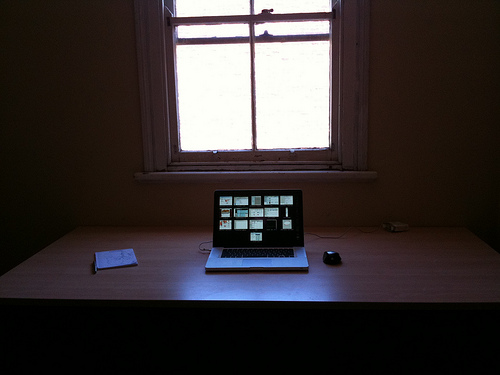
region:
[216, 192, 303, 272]
laptop sitting on wood desk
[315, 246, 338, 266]
black mouse on wood table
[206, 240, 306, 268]
black keyboard on laptop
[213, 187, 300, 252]
illuminated monitor on laptop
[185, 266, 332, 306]
light bouncing off wood table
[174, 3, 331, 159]
glass window above desk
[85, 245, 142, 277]
white paper on wood table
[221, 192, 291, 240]
small pictures on laptop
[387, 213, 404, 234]
small object on wood table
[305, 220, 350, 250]
black electrical cable on table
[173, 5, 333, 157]
a window on the wall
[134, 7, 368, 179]
a white window sill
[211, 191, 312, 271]
the laptop on the desk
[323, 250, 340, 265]
a black computer mouse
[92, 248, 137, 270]
a notebook on the desk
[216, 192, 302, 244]
the screen of the laptop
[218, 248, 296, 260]
the black keyboard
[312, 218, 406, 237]
a wire connected to the computer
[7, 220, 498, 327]
a wooden table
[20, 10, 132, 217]
the wall next to the window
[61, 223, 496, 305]
The desk is wooden.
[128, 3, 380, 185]
Desk under the window.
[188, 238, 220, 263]
Cord plugged into the laptop.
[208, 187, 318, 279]
Laptop on the desk.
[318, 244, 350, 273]
Mouse on the desk.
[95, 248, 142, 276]
Paper on the desk.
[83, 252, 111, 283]
Pencil next to the paper.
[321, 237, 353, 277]
The mouse is wireless.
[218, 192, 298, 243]
Pictures on the screen.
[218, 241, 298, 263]
The keys are black.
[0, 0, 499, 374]
the interior of a room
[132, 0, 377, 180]
white trim around a window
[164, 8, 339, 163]
lower window with a latch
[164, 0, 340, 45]
upper part of a window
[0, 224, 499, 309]
a wooden table top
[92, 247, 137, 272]
a notebook with pen on the table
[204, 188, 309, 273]
a laptop on the table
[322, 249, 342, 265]
a computer mouse on the table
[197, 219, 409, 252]
the laptop's power supply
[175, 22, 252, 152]
a glass window pane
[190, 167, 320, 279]
computer laptop on table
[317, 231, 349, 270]
mouse on a table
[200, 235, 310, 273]
keyboard of a laptop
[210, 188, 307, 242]
screen on the laptop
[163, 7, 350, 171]
a window of a building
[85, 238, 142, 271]
a notebook on a table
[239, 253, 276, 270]
a track pad of the laptop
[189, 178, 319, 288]
a small laptop on a table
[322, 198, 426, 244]
cables on the table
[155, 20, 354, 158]
frame of a window